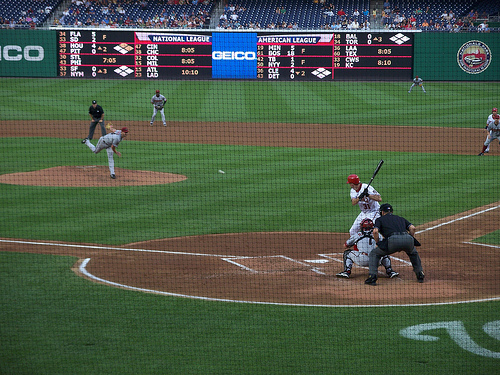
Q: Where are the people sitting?
A: In the stands.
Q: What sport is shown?
A: Baseball.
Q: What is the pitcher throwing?
A: A baseball.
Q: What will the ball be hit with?
A: A bat.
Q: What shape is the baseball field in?
A: A diamond.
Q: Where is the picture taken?
A: Baseball game.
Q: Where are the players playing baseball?
A: Baseball field.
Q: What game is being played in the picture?
A: Baseball.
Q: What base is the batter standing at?
A: First.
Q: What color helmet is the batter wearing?
A: Red.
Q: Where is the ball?
A: The air.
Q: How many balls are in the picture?
A: One.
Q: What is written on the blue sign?
A: GEICO.